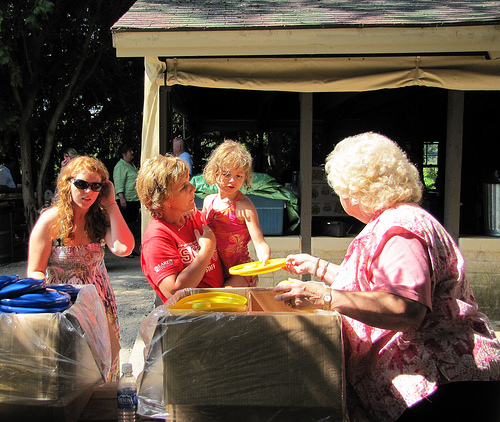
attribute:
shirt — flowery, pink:
[333, 205, 499, 421]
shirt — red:
[138, 213, 228, 305]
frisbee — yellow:
[228, 254, 292, 278]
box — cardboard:
[154, 286, 353, 422]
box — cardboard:
[1, 282, 110, 421]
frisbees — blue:
[0, 274, 79, 322]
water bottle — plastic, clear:
[115, 363, 142, 421]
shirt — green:
[111, 159, 143, 212]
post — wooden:
[442, 85, 466, 248]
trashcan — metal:
[483, 173, 499, 239]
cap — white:
[121, 361, 134, 374]